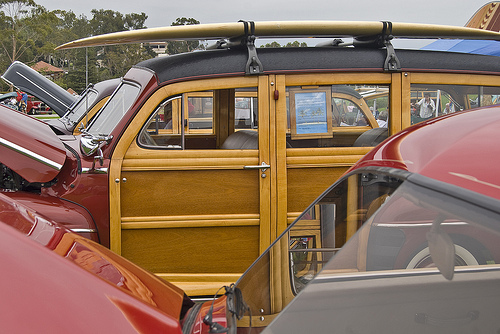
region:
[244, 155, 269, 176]
silver handle of driver's door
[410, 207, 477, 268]
rearview mirror in red car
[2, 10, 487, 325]
three cars with hoods up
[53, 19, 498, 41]
surfboard on top of middle car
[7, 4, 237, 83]
treeds behind three cars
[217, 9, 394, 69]
black brackets on top of car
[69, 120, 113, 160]
side view mirror of car with wood sides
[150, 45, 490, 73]
black top of car with wood side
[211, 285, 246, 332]
windshield wipers of red car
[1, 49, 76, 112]
raised black hood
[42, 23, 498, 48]
surfboard on top of car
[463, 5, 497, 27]
fin on the surfboard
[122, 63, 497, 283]
wooden panelling on the side of car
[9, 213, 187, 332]
hood of the car is up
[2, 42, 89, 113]
black hood is up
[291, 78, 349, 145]
sign on the passenger window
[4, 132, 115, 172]
silver metal strip along the front of the car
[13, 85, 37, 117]
people looking at cars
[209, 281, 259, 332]
windshield wiper on the car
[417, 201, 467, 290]
rearview mirror in the car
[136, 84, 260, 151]
the window on the driver's side of the car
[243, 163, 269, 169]
the handle to the door on the driver's side of the car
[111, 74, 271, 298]
the door to the driver's side of the car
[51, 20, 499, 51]
the surfboard on top of the car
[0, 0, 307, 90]
the tall trees in the distance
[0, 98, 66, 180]
the opened hood on the car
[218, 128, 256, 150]
the backrest to the front seats of the car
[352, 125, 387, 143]
the backrest to the seats in the back of the car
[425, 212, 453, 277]
the rear view mirror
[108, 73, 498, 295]
the wood panel on the side of the car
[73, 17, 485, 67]
surfboard on top of a car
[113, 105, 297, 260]
wooden doors of a car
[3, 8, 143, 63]
many trees growing outside of the field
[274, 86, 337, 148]
blue portrait hung in the window of a car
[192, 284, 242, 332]
black windhiels wipers of the red car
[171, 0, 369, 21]
cloudy grey skies over the field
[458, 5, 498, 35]
patterned wood tailfin of the surfboard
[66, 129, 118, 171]
metal side mirror of a car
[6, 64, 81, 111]
raised black car hood with silver trim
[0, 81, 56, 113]
several people standing away from the cars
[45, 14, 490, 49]
yellow fiberglass surfboard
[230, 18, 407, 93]
brackets holding surfboard on vehicle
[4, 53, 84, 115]
black hood to antique vehicle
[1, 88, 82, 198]
open red hood of antique vehicle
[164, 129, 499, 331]
tinted windshield of antique car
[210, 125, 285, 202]
handle to antique vehicle with wood exterior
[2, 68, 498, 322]
side of antique vehicle with wooden exterior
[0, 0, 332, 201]
trees located behind place where car show is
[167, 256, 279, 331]
black windshield wiper on red car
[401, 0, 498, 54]
tan fin f surfboard with decorative carving like balls on it